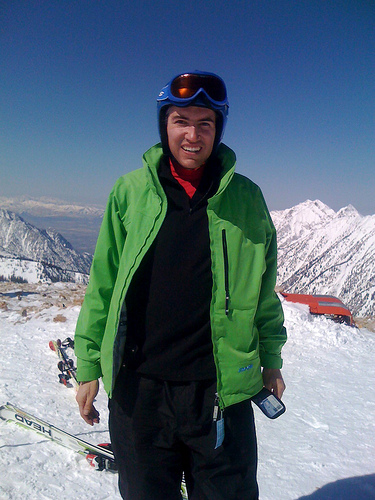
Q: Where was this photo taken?
A: A mountain.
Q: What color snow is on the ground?
A: White.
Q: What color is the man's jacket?
A: Green.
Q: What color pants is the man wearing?
A: Black.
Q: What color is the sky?
A: Blue.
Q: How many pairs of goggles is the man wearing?
A: One.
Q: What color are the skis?
A: White.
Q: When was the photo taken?
A: Daytime.